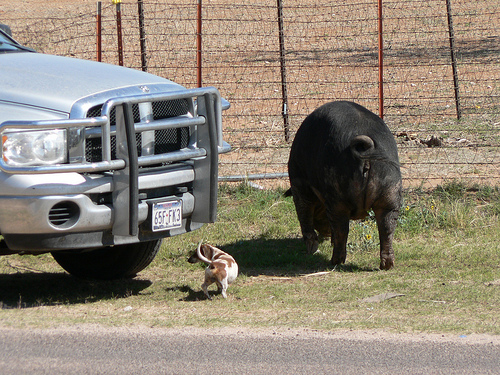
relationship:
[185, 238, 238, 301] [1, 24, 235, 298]
dog in front car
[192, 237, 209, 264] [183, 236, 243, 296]
tail of dog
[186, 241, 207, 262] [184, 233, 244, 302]
face of dog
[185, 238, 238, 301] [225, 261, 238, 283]
dog has black and white spots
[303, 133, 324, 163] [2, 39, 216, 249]
black pig in front truck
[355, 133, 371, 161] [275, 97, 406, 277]
small tail on pig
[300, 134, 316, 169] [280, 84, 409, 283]
back legs of pig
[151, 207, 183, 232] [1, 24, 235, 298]
license plate on car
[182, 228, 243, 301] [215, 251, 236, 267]
dog has brown spots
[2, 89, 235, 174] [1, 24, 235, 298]
grill on car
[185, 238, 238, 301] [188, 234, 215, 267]
dog has tail up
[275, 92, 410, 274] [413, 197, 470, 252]
an animal walking on grass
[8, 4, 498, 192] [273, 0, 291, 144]
fence has post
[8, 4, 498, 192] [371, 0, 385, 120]
fence has post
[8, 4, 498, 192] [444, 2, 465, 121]
fence has post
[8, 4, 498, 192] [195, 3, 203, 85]
fence has post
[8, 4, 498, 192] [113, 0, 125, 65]
fence has post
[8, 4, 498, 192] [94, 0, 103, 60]
fence has post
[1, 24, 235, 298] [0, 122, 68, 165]
car has headlight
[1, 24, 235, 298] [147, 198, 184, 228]
car has plate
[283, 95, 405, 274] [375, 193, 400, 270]
an animal has leg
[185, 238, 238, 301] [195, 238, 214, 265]
dog has tail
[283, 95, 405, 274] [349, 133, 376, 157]
an animal has tail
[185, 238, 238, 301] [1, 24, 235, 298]
dog in front of car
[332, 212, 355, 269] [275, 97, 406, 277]
legs on pig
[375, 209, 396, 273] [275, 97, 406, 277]
legs on pig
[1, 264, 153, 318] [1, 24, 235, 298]
shadow below car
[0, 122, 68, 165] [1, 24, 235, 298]
headlight on car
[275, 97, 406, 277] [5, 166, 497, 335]
pig walking on grass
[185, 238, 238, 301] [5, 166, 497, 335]
dog walking on grass